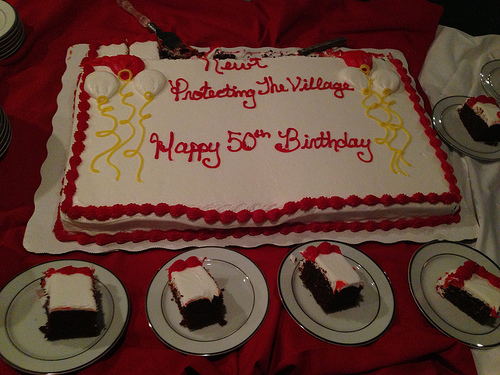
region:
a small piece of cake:
[15, 253, 152, 364]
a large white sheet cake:
[31, 15, 459, 240]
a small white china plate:
[144, 246, 275, 356]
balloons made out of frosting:
[91, 56, 175, 186]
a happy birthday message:
[134, 121, 382, 179]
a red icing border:
[61, 176, 135, 248]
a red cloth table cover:
[30, 0, 54, 81]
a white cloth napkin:
[420, 25, 487, 87]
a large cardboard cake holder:
[7, 153, 59, 250]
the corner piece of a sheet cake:
[402, 139, 469, 236]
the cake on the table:
[75, 45, 447, 232]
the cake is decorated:
[61, 55, 449, 232]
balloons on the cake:
[77, 62, 191, 188]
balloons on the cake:
[345, 57, 420, 182]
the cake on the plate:
[5, 258, 145, 364]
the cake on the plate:
[139, 248, 274, 353]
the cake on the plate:
[271, 240, 401, 348]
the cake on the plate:
[406, 248, 498, 338]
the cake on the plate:
[433, 94, 497, 155]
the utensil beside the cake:
[119, 3, 209, 56]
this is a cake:
[63, 33, 461, 245]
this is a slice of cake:
[42, 247, 107, 346]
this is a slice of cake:
[138, 244, 217, 327]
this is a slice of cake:
[296, 245, 361, 322]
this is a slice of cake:
[420, 251, 490, 346]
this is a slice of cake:
[455, 90, 495, 142]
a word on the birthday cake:
[142, 126, 232, 181]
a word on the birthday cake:
[212, 102, 278, 162]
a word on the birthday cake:
[284, 124, 380, 178]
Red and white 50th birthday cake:
[50, 38, 462, 246]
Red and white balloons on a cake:
[80, 48, 413, 180]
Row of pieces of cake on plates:
[1, 238, 498, 371]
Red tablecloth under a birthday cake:
[7, 5, 480, 374]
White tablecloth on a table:
[416, 21, 497, 372]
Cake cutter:
[116, 1, 189, 51]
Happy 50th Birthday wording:
[147, 124, 374, 169]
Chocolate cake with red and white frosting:
[40, 266, 104, 339]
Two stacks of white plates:
[3, 0, 28, 164]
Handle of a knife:
[285, 34, 350, 55]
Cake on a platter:
[37, 38, 479, 238]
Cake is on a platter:
[21, 40, 486, 246]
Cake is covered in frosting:
[54, 37, 463, 234]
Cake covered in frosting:
[55, 32, 467, 243]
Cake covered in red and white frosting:
[46, 37, 469, 245]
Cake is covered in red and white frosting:
[57, 38, 472, 248]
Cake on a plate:
[146, 248, 248, 334]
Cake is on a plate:
[160, 255, 232, 327]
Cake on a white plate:
[156, 247, 242, 335]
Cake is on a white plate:
[163, 255, 236, 338]